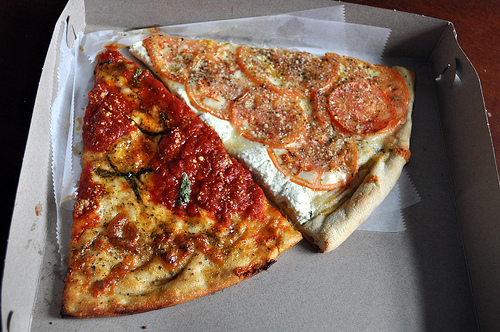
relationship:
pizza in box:
[61, 19, 416, 318] [2, 3, 499, 326]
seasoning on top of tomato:
[149, 37, 379, 169] [329, 80, 395, 143]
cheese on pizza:
[65, 50, 282, 293] [60, 44, 305, 318]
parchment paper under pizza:
[51, 17, 422, 278] [61, 19, 416, 318]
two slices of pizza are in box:
[61, 19, 416, 318] [2, 3, 499, 326]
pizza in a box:
[61, 19, 416, 318] [2, 3, 499, 326]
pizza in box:
[125, 33, 413, 247] [2, 3, 499, 326]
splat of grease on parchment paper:
[25, 221, 64, 307] [51, 17, 422, 278]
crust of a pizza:
[325, 207, 357, 242] [59, 54, 289, 308]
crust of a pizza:
[325, 207, 357, 242] [125, 33, 413, 247]